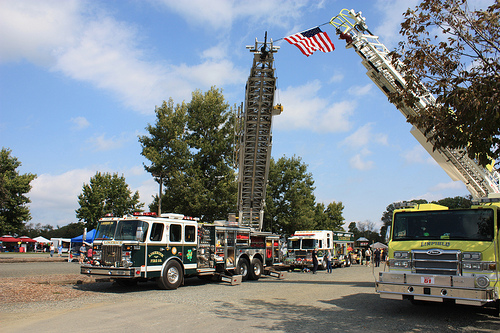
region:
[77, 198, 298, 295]
a fire truck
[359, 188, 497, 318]
another fire truck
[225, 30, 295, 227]
the ladder of the fire truck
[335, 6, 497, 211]
the ladder of the fire truck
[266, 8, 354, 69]
the American flag above the fire trucks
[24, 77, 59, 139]
the clear blue sky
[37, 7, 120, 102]
clouds in the sky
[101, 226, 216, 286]
the fire truck is white and green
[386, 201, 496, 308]
the fire truck is yellow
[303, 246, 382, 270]
people standing on the ground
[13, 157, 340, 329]
the truck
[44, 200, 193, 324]
the truck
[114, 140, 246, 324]
the truck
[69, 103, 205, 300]
the truck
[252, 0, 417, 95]
a flag in the air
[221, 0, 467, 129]
flag being held in the air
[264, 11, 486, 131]
the american flag in the air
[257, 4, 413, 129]
the american flag flying in the air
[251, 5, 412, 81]
red white and blue flag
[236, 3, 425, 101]
red white and blue american flag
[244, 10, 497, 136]
red white and blue flag being held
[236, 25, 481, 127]
red white and blue flying in the air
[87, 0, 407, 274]
a fire truck that is parked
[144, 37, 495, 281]
two fire trucks that are parked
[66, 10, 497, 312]
two firetrucks suspending a flag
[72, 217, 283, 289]
green and white fire truck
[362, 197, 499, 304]
bright yellow fire truck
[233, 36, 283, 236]
tall ladder of fire truck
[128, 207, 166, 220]
lights with sirens on top of fire truck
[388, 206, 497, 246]
front windshield of firetruck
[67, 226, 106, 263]
pop up canopy with blue tarp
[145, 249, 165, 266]
name of fire department on door of truck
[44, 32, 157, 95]
white clouds in the sky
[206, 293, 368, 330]
shadow of tree on road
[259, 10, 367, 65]
us flag in the air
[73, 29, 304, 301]
fire truck with ladder raised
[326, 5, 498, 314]
fire truck with ladder raised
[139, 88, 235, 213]
tall trees with leaves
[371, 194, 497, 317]
yellow colored truck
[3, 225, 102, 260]
structure seen in background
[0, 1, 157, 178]
partly cloudy sky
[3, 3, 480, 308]
picture taken in broad daylight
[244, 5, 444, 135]
flag hanging on fire truck ladder